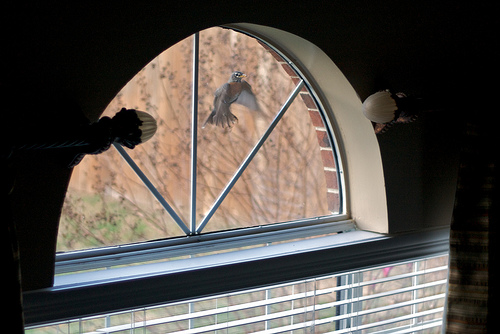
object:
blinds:
[19, 251, 453, 334]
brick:
[325, 187, 341, 214]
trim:
[12, 215, 450, 328]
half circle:
[53, 22, 388, 276]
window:
[23, 250, 446, 334]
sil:
[57, 227, 387, 307]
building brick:
[299, 89, 320, 109]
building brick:
[289, 77, 309, 91]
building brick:
[280, 61, 302, 78]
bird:
[203, 71, 258, 128]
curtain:
[0, 0, 24, 334]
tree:
[208, 129, 325, 216]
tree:
[69, 176, 159, 246]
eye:
[236, 74, 239, 76]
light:
[361, 89, 419, 135]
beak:
[239, 74, 246, 79]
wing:
[214, 82, 232, 104]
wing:
[236, 79, 258, 110]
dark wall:
[3, 6, 92, 311]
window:
[51, 25, 356, 276]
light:
[112, 107, 158, 149]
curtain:
[355, 0, 498, 334]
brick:
[322, 167, 340, 194]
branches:
[271, 124, 321, 218]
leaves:
[97, 216, 122, 237]